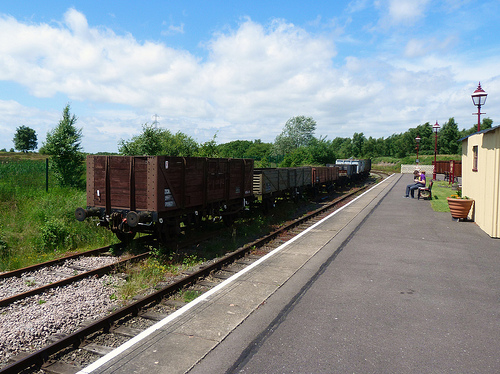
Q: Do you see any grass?
A: Yes, there is grass.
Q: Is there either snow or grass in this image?
A: Yes, there is grass.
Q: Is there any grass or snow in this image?
A: Yes, there is grass.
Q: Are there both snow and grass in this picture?
A: No, there is grass but no snow.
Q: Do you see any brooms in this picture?
A: No, there are no brooms.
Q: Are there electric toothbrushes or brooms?
A: No, there are no brooms or electric toothbrushes.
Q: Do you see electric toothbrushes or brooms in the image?
A: No, there are no brooms or electric toothbrushes.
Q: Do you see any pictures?
A: No, there are no pictures.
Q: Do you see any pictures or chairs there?
A: No, there are no pictures or chairs.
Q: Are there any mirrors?
A: No, there are no mirrors.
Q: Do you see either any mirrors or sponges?
A: No, there are no mirrors or sponges.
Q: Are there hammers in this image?
A: No, there are no hammers.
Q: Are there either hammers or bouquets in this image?
A: No, there are no hammers or bouquets.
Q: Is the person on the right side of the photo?
A: Yes, the person is on the right of the image.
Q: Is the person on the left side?
A: No, the person is on the right of the image.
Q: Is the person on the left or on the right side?
A: The person is on the right of the image.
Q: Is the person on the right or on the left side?
A: The person is on the right of the image.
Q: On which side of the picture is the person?
A: The person is on the right of the image.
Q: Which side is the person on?
A: The person is on the right of the image.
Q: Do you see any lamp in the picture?
A: Yes, there is a lamp.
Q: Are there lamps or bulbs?
A: Yes, there is a lamp.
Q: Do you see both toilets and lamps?
A: No, there is a lamp but no toilets.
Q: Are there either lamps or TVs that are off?
A: Yes, the lamp is off.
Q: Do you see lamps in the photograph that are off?
A: Yes, there is a lamp that is off.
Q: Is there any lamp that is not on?
A: Yes, there is a lamp that is off.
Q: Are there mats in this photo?
A: No, there are no mats.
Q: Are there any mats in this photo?
A: No, there are no mats.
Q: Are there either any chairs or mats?
A: No, there are no mats or chairs.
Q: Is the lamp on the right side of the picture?
A: Yes, the lamp is on the right of the image.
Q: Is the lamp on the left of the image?
A: No, the lamp is on the right of the image.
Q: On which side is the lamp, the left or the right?
A: The lamp is on the right of the image.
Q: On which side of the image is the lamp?
A: The lamp is on the right of the image.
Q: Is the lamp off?
A: Yes, the lamp is off.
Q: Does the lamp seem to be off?
A: Yes, the lamp is off.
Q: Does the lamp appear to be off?
A: Yes, the lamp is off.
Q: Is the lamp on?
A: No, the lamp is off.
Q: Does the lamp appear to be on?
A: No, the lamp is off.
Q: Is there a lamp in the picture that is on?
A: No, there is a lamp but it is off.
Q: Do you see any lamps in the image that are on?
A: No, there is a lamp but it is off.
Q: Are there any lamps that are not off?
A: No, there is a lamp but it is off.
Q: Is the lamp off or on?
A: The lamp is off.